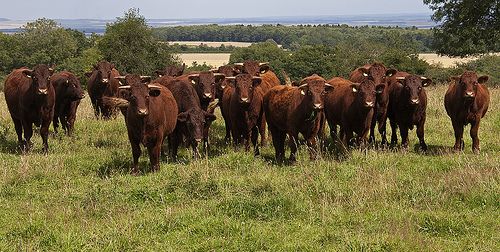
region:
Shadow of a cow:
[96, 153, 154, 180]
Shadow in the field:
[410, 136, 462, 158]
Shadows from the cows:
[0, 118, 462, 178]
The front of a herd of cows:
[3, 58, 490, 175]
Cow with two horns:
[386, 70, 431, 152]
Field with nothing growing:
[162, 50, 232, 68]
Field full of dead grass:
[155, 38, 282, 48]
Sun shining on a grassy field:
[0, 83, 498, 250]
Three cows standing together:
[322, 62, 431, 154]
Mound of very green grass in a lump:
[217, 192, 304, 224]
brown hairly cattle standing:
[133, 71, 485, 156]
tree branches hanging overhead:
[427, 0, 499, 47]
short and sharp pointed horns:
[121, 82, 173, 89]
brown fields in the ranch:
[185, 53, 221, 63]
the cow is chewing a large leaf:
[303, 103, 335, 122]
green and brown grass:
[154, 193, 391, 235]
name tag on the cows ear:
[299, 82, 305, 94]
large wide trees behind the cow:
[6, 13, 159, 60]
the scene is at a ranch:
[1, 2, 498, 249]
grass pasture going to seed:
[0, 115, 497, 249]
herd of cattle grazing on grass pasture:
[1, 65, 496, 171]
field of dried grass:
[166, 50, 233, 70]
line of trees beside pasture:
[0, 8, 497, 88]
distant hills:
[5, 12, 445, 32]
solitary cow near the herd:
[440, 65, 490, 146]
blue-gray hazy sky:
[0, 0, 451, 20]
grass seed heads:
[308, 133, 323, 154]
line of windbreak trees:
[147, 23, 435, 44]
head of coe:
[115, 78, 163, 116]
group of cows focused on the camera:
[46, 43, 481, 181]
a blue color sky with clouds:
[151, 7, 414, 22]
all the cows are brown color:
[22, 60, 477, 141]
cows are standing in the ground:
[20, 38, 492, 225]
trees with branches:
[28, 28, 156, 63]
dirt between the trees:
[192, 24, 340, 69]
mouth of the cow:
[310, 99, 324, 112]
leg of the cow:
[125, 135, 163, 175]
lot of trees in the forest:
[237, 17, 437, 63]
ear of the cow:
[18, 66, 35, 83]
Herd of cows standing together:
[4, 58, 491, 178]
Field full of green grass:
[0, 84, 498, 250]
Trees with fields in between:
[2, 15, 499, 82]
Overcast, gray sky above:
[0, 0, 433, 25]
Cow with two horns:
[115, 78, 177, 177]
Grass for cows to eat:
[0, 72, 497, 250]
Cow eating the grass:
[154, 73, 217, 163]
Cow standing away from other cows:
[442, 70, 490, 155]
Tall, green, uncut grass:
[0, 83, 497, 250]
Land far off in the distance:
[0, 15, 442, 28]